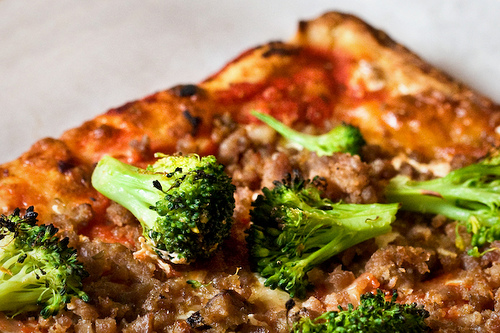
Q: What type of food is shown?
A: Pizza.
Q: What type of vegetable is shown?
A: Broccoli.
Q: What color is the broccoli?
A: Green.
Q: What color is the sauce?
A: Red.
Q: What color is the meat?
A: Brown.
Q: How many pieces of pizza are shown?
A: One.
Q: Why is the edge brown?
A: Pizza is cooked.